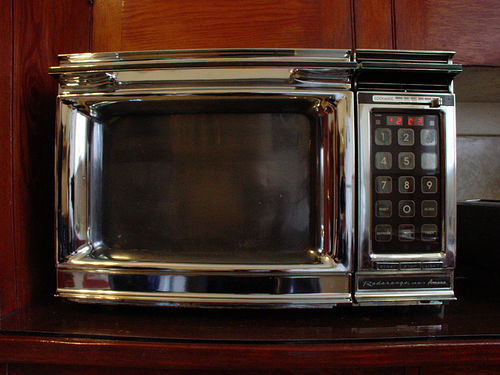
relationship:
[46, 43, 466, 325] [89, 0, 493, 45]
microwave below cabinets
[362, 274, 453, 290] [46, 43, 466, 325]
words on front of microwave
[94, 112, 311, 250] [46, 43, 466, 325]
window on front of microwave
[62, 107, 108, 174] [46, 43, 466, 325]
reflection on microwave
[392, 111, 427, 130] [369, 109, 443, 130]
numbers on display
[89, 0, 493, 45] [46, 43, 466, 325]
cabinets above microwave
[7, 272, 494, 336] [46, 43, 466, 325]
glass under microwave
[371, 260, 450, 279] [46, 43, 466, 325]
buttons on microwave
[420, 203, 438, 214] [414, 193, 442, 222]
word on button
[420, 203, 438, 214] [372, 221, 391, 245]
word on button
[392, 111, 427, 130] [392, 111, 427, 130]
numbers with numbers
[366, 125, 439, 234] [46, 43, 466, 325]
key pad on microwave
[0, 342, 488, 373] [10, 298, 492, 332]
shelf topped with glass